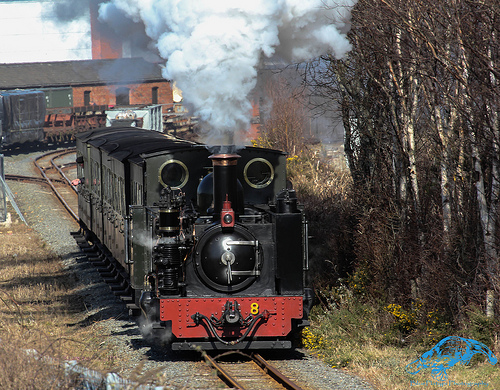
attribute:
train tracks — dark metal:
[201, 352, 296, 388]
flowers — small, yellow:
[331, 246, 386, 312]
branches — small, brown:
[291, 47, 387, 121]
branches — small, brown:
[437, 229, 482, 309]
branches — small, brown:
[389, 182, 444, 314]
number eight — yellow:
[248, 300, 260, 312]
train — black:
[73, 103, 310, 350]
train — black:
[61, 119, 321, 357]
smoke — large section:
[37, 0, 359, 153]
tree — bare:
[429, 2, 499, 294]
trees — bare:
[308, 27, 498, 254]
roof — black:
[0, 56, 175, 90]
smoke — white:
[98, 1, 297, 148]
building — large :
[0, 46, 187, 161]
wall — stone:
[89, 87, 110, 108]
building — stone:
[0, 3, 178, 131]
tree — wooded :
[285, 0, 496, 350]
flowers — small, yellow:
[384, 297, 435, 328]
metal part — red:
[223, 298, 240, 325]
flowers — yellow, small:
[366, 303, 428, 344]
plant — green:
[365, 205, 427, 323]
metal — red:
[220, 237, 260, 252]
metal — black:
[216, 298, 245, 323]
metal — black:
[157, 201, 178, 232]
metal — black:
[211, 152, 246, 202]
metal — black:
[278, 189, 295, 294]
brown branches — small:
[328, 18, 455, 215]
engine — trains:
[69, 129, 310, 361]